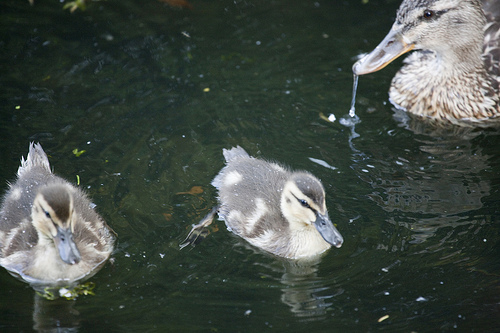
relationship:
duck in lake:
[208, 142, 348, 262] [0, 1, 499, 333]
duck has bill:
[208, 142, 348, 262] [312, 213, 346, 249]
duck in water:
[208, 142, 348, 262] [0, 4, 498, 331]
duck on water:
[208, 142, 348, 262] [0, 4, 498, 331]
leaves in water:
[29, 1, 95, 14] [0, 4, 498, 331]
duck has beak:
[208, 142, 348, 262] [311, 210, 346, 249]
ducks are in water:
[0, 140, 346, 283] [0, 4, 498, 331]